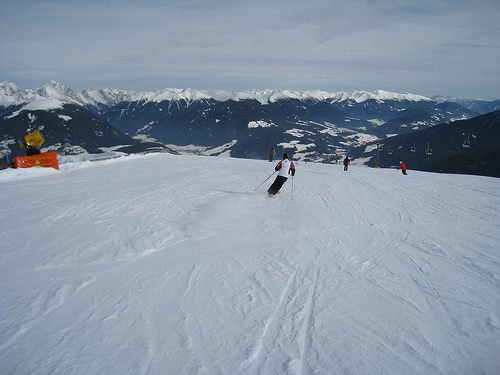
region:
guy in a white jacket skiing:
[257, 150, 298, 198]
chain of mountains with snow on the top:
[1, 80, 431, 126]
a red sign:
[12, 150, 66, 176]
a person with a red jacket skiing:
[395, 157, 410, 174]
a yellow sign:
[20, 125, 47, 150]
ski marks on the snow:
[252, 246, 320, 373]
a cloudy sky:
[0, 3, 498, 77]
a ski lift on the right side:
[369, 117, 498, 168]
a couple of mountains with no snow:
[367, 100, 472, 135]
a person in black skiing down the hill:
[340, 153, 351, 170]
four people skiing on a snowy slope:
[252, 145, 411, 198]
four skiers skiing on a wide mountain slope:
[137, 145, 425, 254]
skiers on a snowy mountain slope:
[238, 145, 411, 199]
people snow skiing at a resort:
[65, 144, 410, 371]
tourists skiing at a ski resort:
[87, 143, 410, 354]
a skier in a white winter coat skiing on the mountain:
[253, 154, 298, 197]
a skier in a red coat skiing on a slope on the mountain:
[395, 158, 408, 177]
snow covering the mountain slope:
[7, 257, 495, 367]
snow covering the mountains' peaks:
[1, 78, 437, 123]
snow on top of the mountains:
[0, 78, 435, 119]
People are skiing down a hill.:
[157, 105, 462, 266]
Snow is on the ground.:
[5, 245, 250, 352]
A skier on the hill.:
[256, 151, 311, 211]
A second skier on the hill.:
[385, 150, 421, 187]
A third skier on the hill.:
[326, 146, 361, 177]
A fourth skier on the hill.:
[260, 142, 277, 162]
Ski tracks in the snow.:
[240, 265, 341, 370]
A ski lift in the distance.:
[367, 120, 489, 166]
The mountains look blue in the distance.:
[165, 105, 220, 135]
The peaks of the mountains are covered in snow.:
[103, 83, 440, 104]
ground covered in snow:
[94, 160, 151, 200]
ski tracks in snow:
[251, 249, 342, 362]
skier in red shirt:
[380, 142, 435, 184]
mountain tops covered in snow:
[149, 74, 439, 114]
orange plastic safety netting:
[13, 152, 67, 174]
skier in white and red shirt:
[253, 153, 318, 211]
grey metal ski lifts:
[401, 128, 483, 155]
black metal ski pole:
[241, 168, 278, 196]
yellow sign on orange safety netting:
[31, 154, 46, 169]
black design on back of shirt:
[280, 157, 290, 164]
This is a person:
[393, 157, 413, 182]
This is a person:
[370, 155, 384, 174]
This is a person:
[340, 153, 353, 174]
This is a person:
[264, 141, 276, 161]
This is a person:
[264, 150, 298, 200]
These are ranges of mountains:
[1, 75, 465, 114]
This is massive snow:
[4, 152, 494, 373]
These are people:
[253, 138, 430, 202]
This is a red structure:
[10, 150, 71, 178]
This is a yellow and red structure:
[2, 124, 73, 193]